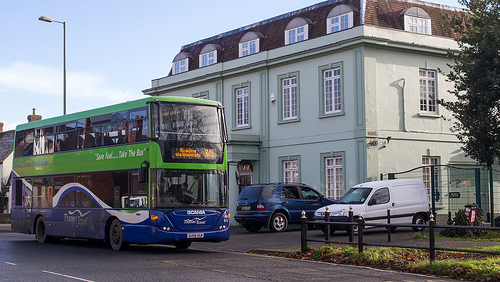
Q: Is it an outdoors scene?
A: Yes, it is outdoors.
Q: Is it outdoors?
A: Yes, it is outdoors.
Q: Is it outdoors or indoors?
A: It is outdoors.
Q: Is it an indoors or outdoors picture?
A: It is outdoors.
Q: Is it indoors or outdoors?
A: It is outdoors.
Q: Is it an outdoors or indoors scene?
A: It is outdoors.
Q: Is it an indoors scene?
A: No, it is outdoors.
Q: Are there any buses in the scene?
A: Yes, there is a bus.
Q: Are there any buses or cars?
A: Yes, there is a bus.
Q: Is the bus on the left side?
A: Yes, the bus is on the left of the image.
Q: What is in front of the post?
A: The bus is in front of the post.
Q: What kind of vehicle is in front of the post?
A: The vehicle is a bus.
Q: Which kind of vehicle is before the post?
A: The vehicle is a bus.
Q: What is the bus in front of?
A: The bus is in front of the post.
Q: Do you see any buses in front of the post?
A: Yes, there is a bus in front of the post.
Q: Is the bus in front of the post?
A: Yes, the bus is in front of the post.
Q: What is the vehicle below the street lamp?
A: The vehicle is a bus.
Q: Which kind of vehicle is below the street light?
A: The vehicle is a bus.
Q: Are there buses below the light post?
A: Yes, there is a bus below the light post.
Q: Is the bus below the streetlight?
A: Yes, the bus is below the streetlight.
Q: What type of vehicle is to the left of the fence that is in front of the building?
A: The vehicle is a bus.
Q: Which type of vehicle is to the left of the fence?
A: The vehicle is a bus.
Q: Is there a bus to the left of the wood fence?
A: Yes, there is a bus to the left of the fence.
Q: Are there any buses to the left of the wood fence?
A: Yes, there is a bus to the left of the fence.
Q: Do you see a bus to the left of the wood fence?
A: Yes, there is a bus to the left of the fence.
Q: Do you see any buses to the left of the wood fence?
A: Yes, there is a bus to the left of the fence.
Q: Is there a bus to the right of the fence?
A: No, the bus is to the left of the fence.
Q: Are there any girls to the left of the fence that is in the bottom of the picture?
A: No, there is a bus to the left of the fence.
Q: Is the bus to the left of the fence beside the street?
A: Yes, the bus is to the left of the fence.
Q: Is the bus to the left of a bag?
A: No, the bus is to the left of the fence.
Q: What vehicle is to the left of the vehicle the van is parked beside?
A: The vehicle is a bus.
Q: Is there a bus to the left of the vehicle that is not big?
A: Yes, there is a bus to the left of the vehicle.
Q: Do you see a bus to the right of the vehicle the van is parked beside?
A: No, the bus is to the left of the vehicle.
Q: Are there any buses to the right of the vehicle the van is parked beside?
A: No, the bus is to the left of the vehicle.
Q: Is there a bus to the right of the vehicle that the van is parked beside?
A: No, the bus is to the left of the vehicle.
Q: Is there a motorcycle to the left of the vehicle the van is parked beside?
A: No, there is a bus to the left of the vehicle.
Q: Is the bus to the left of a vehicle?
A: Yes, the bus is to the left of a vehicle.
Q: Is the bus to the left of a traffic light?
A: No, the bus is to the left of a vehicle.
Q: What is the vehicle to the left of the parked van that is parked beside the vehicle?
A: The vehicle is a bus.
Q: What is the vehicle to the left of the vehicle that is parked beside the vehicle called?
A: The vehicle is a bus.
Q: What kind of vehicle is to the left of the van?
A: The vehicle is a bus.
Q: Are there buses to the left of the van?
A: Yes, there is a bus to the left of the van.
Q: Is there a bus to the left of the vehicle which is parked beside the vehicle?
A: Yes, there is a bus to the left of the van.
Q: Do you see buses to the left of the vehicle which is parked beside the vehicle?
A: Yes, there is a bus to the left of the van.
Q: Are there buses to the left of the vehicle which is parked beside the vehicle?
A: Yes, there is a bus to the left of the van.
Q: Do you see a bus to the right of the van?
A: No, the bus is to the left of the van.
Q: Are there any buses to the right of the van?
A: No, the bus is to the left of the van.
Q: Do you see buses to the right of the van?
A: No, the bus is to the left of the van.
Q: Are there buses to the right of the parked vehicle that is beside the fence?
A: No, the bus is to the left of the van.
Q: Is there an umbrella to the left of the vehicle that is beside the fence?
A: No, there is a bus to the left of the van.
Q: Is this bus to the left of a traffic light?
A: No, the bus is to the left of a van.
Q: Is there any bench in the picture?
A: No, there are no benches.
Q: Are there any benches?
A: No, there are no benches.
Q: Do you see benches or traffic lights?
A: No, there are no benches or traffic lights.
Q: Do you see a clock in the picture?
A: No, there are no clocks.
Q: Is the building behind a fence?
A: Yes, the building is behind a fence.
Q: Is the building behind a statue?
A: No, the building is behind a fence.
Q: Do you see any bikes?
A: No, there are no bikes.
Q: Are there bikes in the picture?
A: No, there are no bikes.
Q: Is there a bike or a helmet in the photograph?
A: No, there are no bikes or helmets.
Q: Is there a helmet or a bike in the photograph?
A: No, there are no bikes or helmets.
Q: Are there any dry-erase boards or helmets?
A: No, there are no helmets or dry-erase boards.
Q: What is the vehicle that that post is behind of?
A: The vehicle is a bus.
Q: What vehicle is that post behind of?
A: The post is behind the bus.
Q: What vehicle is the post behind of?
A: The post is behind the bus.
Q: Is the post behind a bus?
A: Yes, the post is behind a bus.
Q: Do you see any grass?
A: Yes, there is grass.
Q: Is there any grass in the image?
A: Yes, there is grass.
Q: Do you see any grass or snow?
A: Yes, there is grass.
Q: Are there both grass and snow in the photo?
A: No, there is grass but no snow.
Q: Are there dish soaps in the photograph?
A: No, there are no dish soaps.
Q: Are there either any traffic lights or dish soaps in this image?
A: No, there are no dish soaps or traffic lights.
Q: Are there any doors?
A: Yes, there is a door.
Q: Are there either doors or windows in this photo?
A: Yes, there is a door.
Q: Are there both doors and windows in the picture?
A: Yes, there are both a door and a window.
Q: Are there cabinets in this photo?
A: No, there are no cabinets.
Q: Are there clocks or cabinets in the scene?
A: No, there are no cabinets or clocks.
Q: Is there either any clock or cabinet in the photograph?
A: No, there are no cabinets or clocks.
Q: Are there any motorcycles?
A: No, there are no motorcycles.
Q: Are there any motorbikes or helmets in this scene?
A: No, there are no motorbikes or helmets.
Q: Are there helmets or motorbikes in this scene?
A: No, there are no motorbikes or helmets.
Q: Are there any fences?
A: Yes, there is a fence.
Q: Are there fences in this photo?
A: Yes, there is a fence.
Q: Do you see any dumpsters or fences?
A: Yes, there is a fence.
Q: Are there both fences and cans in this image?
A: No, there is a fence but no cans.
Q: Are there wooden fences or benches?
A: Yes, there is a wood fence.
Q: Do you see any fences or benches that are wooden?
A: Yes, the fence is wooden.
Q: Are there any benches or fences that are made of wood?
A: Yes, the fence is made of wood.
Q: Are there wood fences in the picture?
A: Yes, there is a wood fence.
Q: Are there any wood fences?
A: Yes, there is a wood fence.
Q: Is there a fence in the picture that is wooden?
A: Yes, there is a fence that is wooden.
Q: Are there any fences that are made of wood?
A: Yes, there is a fence that is made of wood.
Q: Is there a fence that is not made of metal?
A: Yes, there is a fence that is made of wood.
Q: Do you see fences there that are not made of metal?
A: Yes, there is a fence that is made of wood.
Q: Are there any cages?
A: No, there are no cages.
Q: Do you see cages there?
A: No, there are no cages.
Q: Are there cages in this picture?
A: No, there are no cages.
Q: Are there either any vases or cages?
A: No, there are no cages or vases.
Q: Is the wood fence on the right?
A: Yes, the fence is on the right of the image.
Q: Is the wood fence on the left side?
A: No, the fence is on the right of the image.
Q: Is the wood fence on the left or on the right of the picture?
A: The fence is on the right of the image.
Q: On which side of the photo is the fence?
A: The fence is on the right of the image.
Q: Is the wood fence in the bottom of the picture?
A: Yes, the fence is in the bottom of the image.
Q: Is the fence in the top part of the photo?
A: No, the fence is in the bottom of the image.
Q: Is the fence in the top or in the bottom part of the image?
A: The fence is in the bottom of the image.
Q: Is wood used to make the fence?
A: Yes, the fence is made of wood.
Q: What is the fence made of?
A: The fence is made of wood.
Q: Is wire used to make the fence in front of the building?
A: No, the fence is made of wood.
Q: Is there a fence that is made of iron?
A: No, there is a fence but it is made of wood.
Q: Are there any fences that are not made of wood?
A: No, there is a fence but it is made of wood.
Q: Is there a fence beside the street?
A: Yes, there is a fence beside the street.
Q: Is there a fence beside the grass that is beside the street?
A: Yes, there is a fence beside the grass.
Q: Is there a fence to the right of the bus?
A: Yes, there is a fence to the right of the bus.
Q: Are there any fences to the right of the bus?
A: Yes, there is a fence to the right of the bus.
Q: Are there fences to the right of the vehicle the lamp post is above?
A: Yes, there is a fence to the right of the bus.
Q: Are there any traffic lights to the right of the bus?
A: No, there is a fence to the right of the bus.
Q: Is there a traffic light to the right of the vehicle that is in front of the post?
A: No, there is a fence to the right of the bus.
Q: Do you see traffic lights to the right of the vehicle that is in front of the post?
A: No, there is a fence to the right of the bus.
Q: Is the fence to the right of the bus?
A: Yes, the fence is to the right of the bus.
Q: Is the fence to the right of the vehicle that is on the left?
A: Yes, the fence is to the right of the bus.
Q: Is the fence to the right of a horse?
A: No, the fence is to the right of the bus.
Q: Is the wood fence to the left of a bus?
A: No, the fence is to the right of a bus.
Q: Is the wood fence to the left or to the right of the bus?
A: The fence is to the right of the bus.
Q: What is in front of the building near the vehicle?
A: The fence is in front of the building.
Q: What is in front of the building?
A: The fence is in front of the building.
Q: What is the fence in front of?
A: The fence is in front of the building.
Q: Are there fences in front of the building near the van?
A: Yes, there is a fence in front of the building.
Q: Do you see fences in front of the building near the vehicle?
A: Yes, there is a fence in front of the building.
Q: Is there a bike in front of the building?
A: No, there is a fence in front of the building.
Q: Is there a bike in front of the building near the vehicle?
A: No, there is a fence in front of the building.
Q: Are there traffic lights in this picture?
A: No, there are no traffic lights.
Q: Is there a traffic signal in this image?
A: No, there are no traffic lights.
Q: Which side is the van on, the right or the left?
A: The van is on the right of the image.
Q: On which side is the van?
A: The van is on the right of the image.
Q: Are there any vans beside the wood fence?
A: Yes, there is a van beside the fence.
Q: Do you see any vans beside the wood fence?
A: Yes, there is a van beside the fence.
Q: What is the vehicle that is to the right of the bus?
A: The vehicle is a van.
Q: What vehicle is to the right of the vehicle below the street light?
A: The vehicle is a van.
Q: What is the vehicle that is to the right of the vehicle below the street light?
A: The vehicle is a van.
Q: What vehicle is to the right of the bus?
A: The vehicle is a van.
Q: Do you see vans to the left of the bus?
A: No, the van is to the right of the bus.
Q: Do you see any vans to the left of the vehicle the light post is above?
A: No, the van is to the right of the bus.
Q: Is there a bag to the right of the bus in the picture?
A: No, there is a van to the right of the bus.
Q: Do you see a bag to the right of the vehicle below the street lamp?
A: No, there is a van to the right of the bus.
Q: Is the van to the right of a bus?
A: Yes, the van is to the right of a bus.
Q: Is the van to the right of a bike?
A: No, the van is to the right of a bus.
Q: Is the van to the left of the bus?
A: No, the van is to the right of the bus.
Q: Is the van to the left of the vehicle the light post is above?
A: No, the van is to the right of the bus.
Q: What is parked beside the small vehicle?
A: The van is parked beside the vehicle.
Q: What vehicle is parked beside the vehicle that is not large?
A: The vehicle is a van.